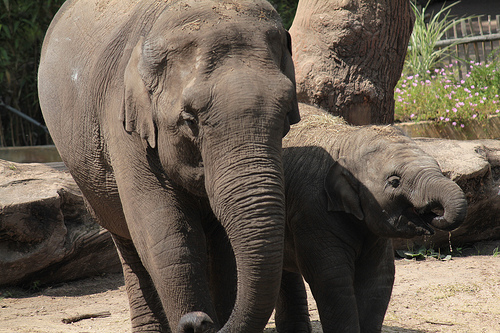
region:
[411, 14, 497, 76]
wood posts of fence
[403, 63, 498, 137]
wildflowers behind cement wall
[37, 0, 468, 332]
adult and baby elephant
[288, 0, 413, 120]
bark on tree trunk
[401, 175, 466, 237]
curled trunk of elephant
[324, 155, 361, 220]
ear of baby elephant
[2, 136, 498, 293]
stone wall in enclosure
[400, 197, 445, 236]
open mouth of elephant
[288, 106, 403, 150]
hay on elephant back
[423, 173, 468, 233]
The trunk of the small elephant.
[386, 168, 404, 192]
The eye of the small elephant.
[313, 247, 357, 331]
The front left leg of the elephant.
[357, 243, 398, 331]
The front right leg of the elephant.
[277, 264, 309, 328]
The back leg of the small elephant.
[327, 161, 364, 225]
The left ear of the small elephant.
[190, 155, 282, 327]
The trunk of the large elephant.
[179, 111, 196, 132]
The left eye of the large elephant.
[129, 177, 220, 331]
The front left leg of the large elephant.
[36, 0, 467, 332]
Mother and baby elephant in the sunshine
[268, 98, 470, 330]
Young elephant with hay on its back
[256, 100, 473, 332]
Young elephant with its trunk bent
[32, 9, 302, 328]
Elephant with its trunk hanging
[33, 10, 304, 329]
Elephant walking with its trunk swinging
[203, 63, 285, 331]
A very wrinkled elephant's trunk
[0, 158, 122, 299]
Large rock sitting on the ground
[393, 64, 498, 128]
A group of pink wildflowers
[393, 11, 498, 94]
A wooden fence in the background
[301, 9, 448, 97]
Large tree trunk with foliage in the background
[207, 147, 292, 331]
The trunk of the larger elephant.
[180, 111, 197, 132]
The eye of the larger elephant.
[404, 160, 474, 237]
curled baby elephant trunk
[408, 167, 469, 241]
curled trunk on baby elephant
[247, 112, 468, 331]
young elephant near older elephant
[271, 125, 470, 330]
baby elephant facing right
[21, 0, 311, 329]
large elephant facing forward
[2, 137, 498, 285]
low rock ridge behind elephants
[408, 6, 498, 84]
distant fence beyond flowers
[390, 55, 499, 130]
pink flowers near tree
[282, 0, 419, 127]
brown gnarled tree trunk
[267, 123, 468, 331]
baby elephant to right of large elephant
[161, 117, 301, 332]
large adult elephant trunk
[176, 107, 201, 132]
eye is on head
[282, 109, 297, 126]
eye is on head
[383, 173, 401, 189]
eye is on head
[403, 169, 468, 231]
trunk is on head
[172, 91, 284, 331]
trunk is on head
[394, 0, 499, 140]
vegetation is in background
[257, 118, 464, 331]
baby elephant to the right of older elephant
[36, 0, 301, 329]
large elephant to left of baby elephant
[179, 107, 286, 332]
trunk hangs down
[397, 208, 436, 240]
mouth is open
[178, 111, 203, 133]
eye belongs to elephant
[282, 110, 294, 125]
eye belongs to elephant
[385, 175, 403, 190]
eye belongs to elephant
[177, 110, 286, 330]
trunk belongs to elephant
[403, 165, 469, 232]
trunk belongs to elephant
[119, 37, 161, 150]
ear belongs to elephant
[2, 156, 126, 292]
rock is behind elephant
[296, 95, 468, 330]
elephant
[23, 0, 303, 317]
elephant